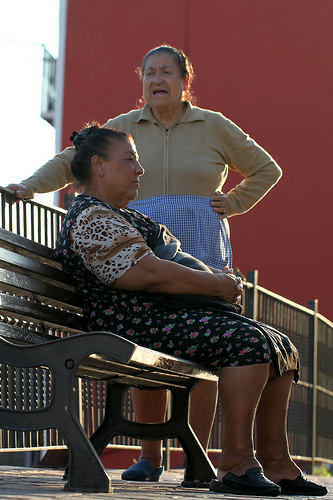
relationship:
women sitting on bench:
[54, 121, 327, 497] [2, 229, 220, 494]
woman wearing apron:
[5, 44, 284, 485] [126, 195, 231, 270]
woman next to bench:
[5, 44, 284, 485] [2, 229, 220, 494]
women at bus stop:
[0, 45, 329, 497] [2, 42, 331, 500]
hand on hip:
[210, 188, 230, 222] [202, 195, 231, 243]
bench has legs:
[2, 229, 220, 494] [0, 373, 217, 500]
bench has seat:
[2, 229, 220, 494] [28, 330, 217, 394]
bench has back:
[2, 229, 220, 494] [0, 228, 86, 343]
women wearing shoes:
[54, 121, 327, 497] [210, 467, 328, 496]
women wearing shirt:
[54, 121, 327, 497] [69, 201, 153, 285]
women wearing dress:
[54, 121, 327, 497] [56, 193, 302, 384]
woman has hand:
[5, 44, 284, 485] [2, 183, 34, 204]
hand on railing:
[2, 183, 34, 204] [0, 45, 329, 497]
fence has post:
[0, 186, 332, 468] [247, 269, 259, 322]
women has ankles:
[54, 121, 327, 497] [213, 445, 305, 481]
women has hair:
[54, 121, 327, 497] [67, 122, 133, 184]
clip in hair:
[69, 131, 81, 145] [67, 122, 133, 184]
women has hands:
[54, 121, 327, 497] [217, 262, 244, 302]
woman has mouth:
[5, 44, 284, 485] [152, 88, 170, 96]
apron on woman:
[126, 195, 231, 270] [5, 44, 284, 485]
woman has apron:
[5, 44, 284, 485] [126, 195, 231, 270]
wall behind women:
[59, 4, 332, 470] [0, 45, 329, 497]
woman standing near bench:
[5, 44, 284, 485] [2, 229, 220, 494]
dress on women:
[56, 193, 302, 384] [54, 121, 327, 497]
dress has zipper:
[18, 103, 286, 216] [159, 126, 171, 195]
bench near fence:
[2, 229, 220, 494] [0, 186, 332, 468]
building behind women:
[2, 3, 329, 469] [0, 45, 329, 497]